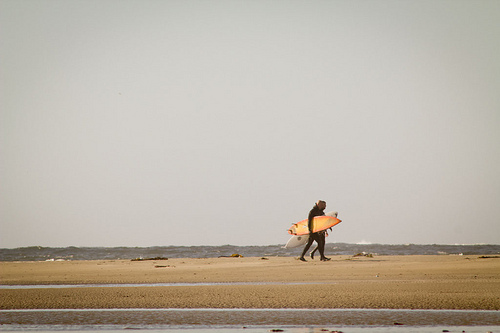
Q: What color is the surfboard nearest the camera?
A: Orange.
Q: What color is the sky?
A: White.